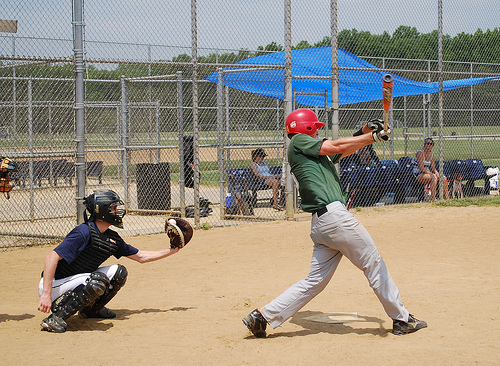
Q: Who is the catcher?
A: The kid in the black shirt.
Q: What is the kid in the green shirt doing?
A: Swinging a bat.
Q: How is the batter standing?
A: With his legs apart.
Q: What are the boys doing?
A: Playing baseball.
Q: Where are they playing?
A: At a ball field.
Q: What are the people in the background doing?
A: Sitting and watching.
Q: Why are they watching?
A: Their kids are playing.